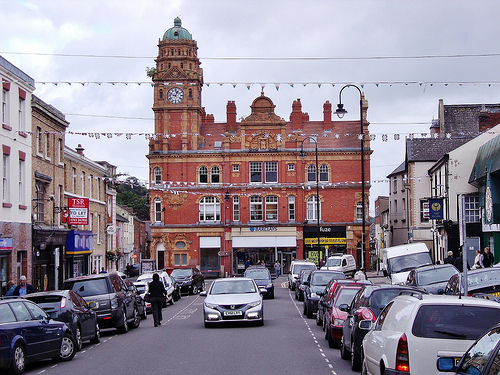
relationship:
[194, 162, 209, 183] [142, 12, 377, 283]
window on building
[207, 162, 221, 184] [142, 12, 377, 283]
window on building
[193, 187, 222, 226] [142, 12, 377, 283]
window on building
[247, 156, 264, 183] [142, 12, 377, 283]
window on building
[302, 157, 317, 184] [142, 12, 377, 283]
window on building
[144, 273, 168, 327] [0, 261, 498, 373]
lady on street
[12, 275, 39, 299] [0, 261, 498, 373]
people on street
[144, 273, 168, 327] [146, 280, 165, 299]
lady wears shirt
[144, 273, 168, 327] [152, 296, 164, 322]
lady wears pants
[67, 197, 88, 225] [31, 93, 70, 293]
banner to building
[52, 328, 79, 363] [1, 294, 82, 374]
tire of car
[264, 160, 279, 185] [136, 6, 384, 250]
window of building